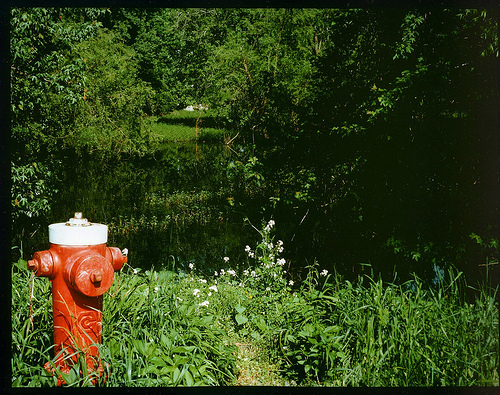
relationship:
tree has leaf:
[9, 3, 76, 256] [54, 77, 66, 93]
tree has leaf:
[9, 3, 76, 256] [19, 19, 32, 33]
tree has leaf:
[9, 3, 76, 256] [58, 61, 74, 77]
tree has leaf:
[9, 3, 76, 256] [85, 22, 96, 34]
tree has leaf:
[9, 3, 76, 256] [18, 171, 32, 182]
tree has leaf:
[197, 35, 282, 148] [208, 71, 219, 79]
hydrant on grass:
[27, 205, 128, 386] [29, 353, 130, 389]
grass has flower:
[187, 297, 310, 337] [209, 283, 219, 293]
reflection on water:
[88, 163, 169, 199] [42, 153, 402, 277]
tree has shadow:
[197, 35, 282, 148] [155, 109, 245, 135]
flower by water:
[209, 283, 219, 293] [42, 153, 402, 277]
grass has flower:
[263, 282, 495, 350] [432, 261, 448, 282]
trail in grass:
[226, 334, 282, 392] [187, 297, 310, 337]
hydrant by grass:
[27, 205, 128, 386] [29, 353, 130, 389]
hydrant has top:
[27, 205, 128, 386] [46, 209, 111, 249]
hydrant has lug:
[27, 205, 128, 386] [90, 270, 105, 285]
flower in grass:
[209, 283, 219, 293] [187, 297, 310, 337]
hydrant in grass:
[27, 205, 128, 386] [29, 353, 130, 389]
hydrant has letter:
[27, 205, 128, 386] [74, 308, 99, 332]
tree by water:
[9, 3, 76, 256] [42, 153, 402, 277]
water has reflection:
[42, 153, 402, 277] [88, 163, 169, 199]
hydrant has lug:
[27, 205, 128, 386] [69, 208, 90, 225]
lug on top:
[69, 208, 90, 225] [46, 209, 111, 249]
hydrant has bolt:
[27, 205, 128, 386] [69, 208, 90, 225]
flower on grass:
[209, 283, 219, 293] [187, 297, 310, 337]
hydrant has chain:
[27, 205, 128, 386] [28, 272, 34, 343]